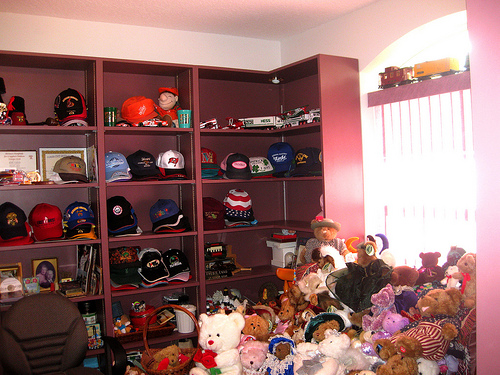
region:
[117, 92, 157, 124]
hat on a shelf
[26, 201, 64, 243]
hat on a shelf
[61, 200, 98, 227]
hat on a shelf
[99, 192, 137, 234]
hat on a shelf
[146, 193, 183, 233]
hat on a shelf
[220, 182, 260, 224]
hat on a shelf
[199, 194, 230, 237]
hat on a shelf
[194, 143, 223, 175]
hat on a shelf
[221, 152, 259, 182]
hat on a shelf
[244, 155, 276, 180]
hat on a shelf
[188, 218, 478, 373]
collection of stuffed animals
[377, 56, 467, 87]
toy train above window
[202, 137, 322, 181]
shelf holding part of a ball cap collection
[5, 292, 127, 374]
chair in front of shelves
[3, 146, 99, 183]
ball caps and certificates on shelf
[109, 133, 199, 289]
three shelves full of ball caps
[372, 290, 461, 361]
teddy bear in patriotic clothing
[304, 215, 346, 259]
teddy bear wearing hat with pink flower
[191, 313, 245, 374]
white teddy bear holding red roses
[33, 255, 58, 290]
framed photo on shelf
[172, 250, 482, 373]
bunch of stuffed animals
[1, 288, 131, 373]
black chair with black armrests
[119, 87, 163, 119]
orange hat on top shelf of bookcase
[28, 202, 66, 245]
red hat on fourth shelf of bookcase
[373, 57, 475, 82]
trains on the shelf above window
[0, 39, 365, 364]
shelves with hats on them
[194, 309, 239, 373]
white bear with red nose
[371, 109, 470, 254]
window behind stuffed animals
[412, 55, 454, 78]
yellow train car above window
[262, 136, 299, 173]
blue hat on bookshelf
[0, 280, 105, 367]
Black computer chair in the corner.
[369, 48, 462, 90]
Train on a shelf.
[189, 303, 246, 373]
White teddy bear holding flowers.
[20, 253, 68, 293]
Picture in a frame.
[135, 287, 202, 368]
Basket with a teddy bear.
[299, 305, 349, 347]
Dora the Explorer doll.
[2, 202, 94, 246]
Shelf filled with ball caps.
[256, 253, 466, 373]
Corner filled with stuffed toys.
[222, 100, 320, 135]
Toy trucks on the shelf.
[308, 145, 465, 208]
Sunlight streaming into the room.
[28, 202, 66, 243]
Red hat on shelf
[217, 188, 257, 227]
Hat with american flag print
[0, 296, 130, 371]
Black office chair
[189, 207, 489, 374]
Pile of teddy bears on floor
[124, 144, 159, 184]
Black hat on shelf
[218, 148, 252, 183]
Black and pink hat on shelf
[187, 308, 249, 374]
White teddy bear on floor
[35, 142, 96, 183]
Certificate behind a shelf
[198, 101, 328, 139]
Toys on top shelf